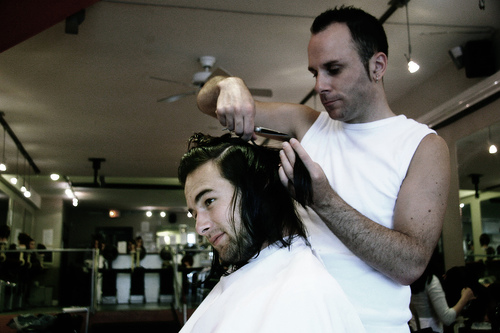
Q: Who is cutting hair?
A: A man.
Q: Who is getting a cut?
A: A man.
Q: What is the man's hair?
A: Black.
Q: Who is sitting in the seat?
A: A man.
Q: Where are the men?
A: In a salon.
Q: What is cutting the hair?
A: Scissors.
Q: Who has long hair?
A: The man sitting down.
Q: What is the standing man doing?
A: Cutting the other man's hair.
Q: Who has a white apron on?
A: The sitting man.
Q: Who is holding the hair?
A: The standing man.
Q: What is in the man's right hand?
A: A comb.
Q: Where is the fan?
A: On the ceiling.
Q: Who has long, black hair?
A: The sitting man.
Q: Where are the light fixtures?
A: Hanging from the ceiling.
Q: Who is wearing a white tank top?
A: The standing man.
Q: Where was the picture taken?
A: At a hair salon.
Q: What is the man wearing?
A: A white apron.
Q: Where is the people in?
A: Salon.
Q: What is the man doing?
A: Getting his hair cut.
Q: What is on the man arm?
A: Hair.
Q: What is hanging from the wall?
A: Light fixtures.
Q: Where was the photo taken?
A: Barber shop.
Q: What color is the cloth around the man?
A: White.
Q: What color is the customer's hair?
A: Black.